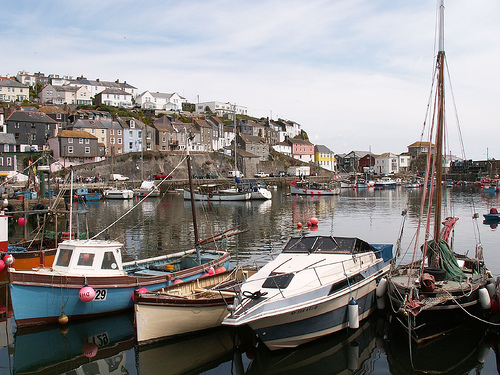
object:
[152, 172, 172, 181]
red truck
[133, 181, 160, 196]
boat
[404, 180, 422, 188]
boat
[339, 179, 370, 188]
boat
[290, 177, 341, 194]
boat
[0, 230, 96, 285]
boat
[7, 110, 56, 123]
roof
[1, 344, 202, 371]
water surface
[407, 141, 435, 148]
roof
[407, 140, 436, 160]
building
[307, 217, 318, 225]
fishing ball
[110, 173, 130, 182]
truck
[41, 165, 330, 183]
road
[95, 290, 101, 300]
number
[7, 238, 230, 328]
boat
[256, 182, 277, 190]
boat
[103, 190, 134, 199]
boat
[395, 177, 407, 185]
boat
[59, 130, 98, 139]
roof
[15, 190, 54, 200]
boat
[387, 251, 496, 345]
boat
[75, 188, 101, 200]
boat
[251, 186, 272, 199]
boat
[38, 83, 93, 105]
buildings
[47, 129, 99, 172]
building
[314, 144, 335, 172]
building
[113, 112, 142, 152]
building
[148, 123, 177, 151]
building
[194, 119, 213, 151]
building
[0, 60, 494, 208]
village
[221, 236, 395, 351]
boat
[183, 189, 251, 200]
boat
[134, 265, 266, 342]
boat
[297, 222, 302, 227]
fishing ball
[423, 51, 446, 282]
mast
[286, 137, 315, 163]
building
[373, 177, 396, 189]
boat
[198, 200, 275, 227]
water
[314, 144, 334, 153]
roof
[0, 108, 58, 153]
building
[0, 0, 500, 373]
picture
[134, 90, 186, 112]
buildings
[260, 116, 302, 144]
houses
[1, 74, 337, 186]
hill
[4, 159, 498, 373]
harbor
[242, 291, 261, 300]
bow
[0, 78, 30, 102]
building